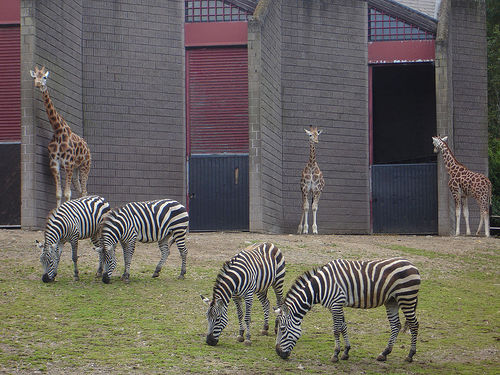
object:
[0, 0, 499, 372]
scene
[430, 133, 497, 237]
giraffe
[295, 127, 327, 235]
giraffe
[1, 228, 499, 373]
field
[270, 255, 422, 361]
zebra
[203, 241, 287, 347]
zebra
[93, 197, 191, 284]
zebra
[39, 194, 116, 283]
zebra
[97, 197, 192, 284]
animal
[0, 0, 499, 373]
outdoors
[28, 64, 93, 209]
giraffe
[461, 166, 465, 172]
spots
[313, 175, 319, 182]
spots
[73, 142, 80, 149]
spots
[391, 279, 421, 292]
stripes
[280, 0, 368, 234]
wall